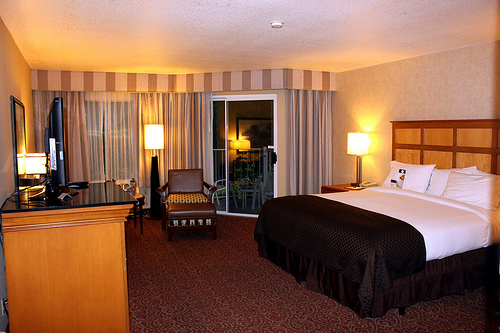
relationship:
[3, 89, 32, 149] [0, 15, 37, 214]
picture on wall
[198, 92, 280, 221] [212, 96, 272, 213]
door leads out to patio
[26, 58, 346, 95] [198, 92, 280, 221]
striped valance over door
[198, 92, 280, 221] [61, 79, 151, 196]
door and window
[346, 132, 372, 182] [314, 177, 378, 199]
lamp on desk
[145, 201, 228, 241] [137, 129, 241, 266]
rest in front of chair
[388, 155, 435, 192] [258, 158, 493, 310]
pillow on bed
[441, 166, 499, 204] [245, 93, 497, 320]
pillow on bed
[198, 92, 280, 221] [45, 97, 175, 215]
door near window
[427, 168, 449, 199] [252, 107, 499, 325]
pillowcases on bed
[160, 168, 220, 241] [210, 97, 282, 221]
chair by glass door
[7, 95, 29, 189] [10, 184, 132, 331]
television on dresser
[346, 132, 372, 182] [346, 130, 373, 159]
lamp with a white lampshade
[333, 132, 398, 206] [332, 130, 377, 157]
lamp with shade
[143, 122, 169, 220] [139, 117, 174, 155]
lamp with shade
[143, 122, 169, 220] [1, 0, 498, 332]
lamp in room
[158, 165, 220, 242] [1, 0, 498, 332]
chair in room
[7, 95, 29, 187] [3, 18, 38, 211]
image on wall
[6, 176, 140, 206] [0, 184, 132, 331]
surface on dresser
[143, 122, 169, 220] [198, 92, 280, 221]
lamp next to door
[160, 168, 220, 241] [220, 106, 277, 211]
chair near a window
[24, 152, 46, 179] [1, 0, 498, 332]
lamp in a room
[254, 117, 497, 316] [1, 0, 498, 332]
bed in room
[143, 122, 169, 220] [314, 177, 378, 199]
lamp on desk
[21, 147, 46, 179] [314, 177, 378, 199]
lamp on desk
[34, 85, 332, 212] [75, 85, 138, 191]
brown drapes on window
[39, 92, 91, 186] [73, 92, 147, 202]
drape for window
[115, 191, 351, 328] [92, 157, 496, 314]
carpet on floor